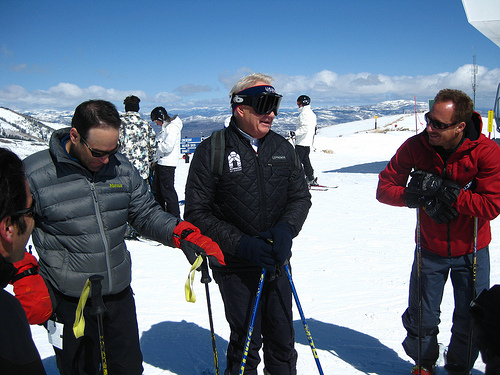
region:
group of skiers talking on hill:
[24, 74, 481, 374]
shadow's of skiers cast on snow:
[116, 283, 435, 373]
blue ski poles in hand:
[208, 263, 370, 365]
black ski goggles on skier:
[226, 79, 305, 126]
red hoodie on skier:
[360, 139, 485, 279]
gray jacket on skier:
[3, 142, 196, 296]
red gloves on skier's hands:
[172, 224, 224, 269]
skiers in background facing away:
[111, 95, 353, 179]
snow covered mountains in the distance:
[38, 80, 425, 160]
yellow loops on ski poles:
[66, 279, 98, 334]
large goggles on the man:
[248, 92, 291, 114]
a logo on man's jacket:
[227, 152, 241, 175]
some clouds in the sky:
[342, 68, 419, 96]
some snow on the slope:
[329, 215, 394, 277]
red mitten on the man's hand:
[180, 226, 215, 258]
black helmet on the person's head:
[152, 108, 169, 118]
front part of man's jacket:
[47, 198, 128, 282]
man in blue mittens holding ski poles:
[242, 238, 314, 374]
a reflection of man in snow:
[326, 319, 386, 372]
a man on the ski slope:
[380, 85, 499, 372]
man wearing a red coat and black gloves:
[408, 88, 489, 260]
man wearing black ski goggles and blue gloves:
[218, 77, 292, 282]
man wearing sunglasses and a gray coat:
[38, 101, 130, 286]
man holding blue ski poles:
[223, 72, 325, 373]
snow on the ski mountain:
[313, 208, 399, 316]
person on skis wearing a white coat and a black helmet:
[294, 93, 319, 188]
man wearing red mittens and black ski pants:
[36, 100, 224, 370]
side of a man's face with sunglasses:
[0, 146, 35, 265]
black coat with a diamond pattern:
[192, 128, 312, 249]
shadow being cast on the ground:
[326, 315, 404, 371]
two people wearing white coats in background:
[151, 93, 358, 213]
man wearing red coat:
[375, 88, 499, 274]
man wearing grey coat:
[19, 97, 228, 331]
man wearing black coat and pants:
[181, 66, 328, 368]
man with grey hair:
[176, 64, 322, 369]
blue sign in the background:
[170, 132, 210, 164]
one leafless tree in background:
[463, 48, 486, 128]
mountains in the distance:
[17, 95, 489, 137]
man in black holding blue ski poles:
[198, 64, 340, 364]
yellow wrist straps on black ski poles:
[55, 249, 213, 336]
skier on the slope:
[201, 54, 294, 374]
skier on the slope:
[384, 80, 486, 365]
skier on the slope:
[37, 93, 174, 373]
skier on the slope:
[153, 97, 190, 220]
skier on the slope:
[110, 93, 152, 181]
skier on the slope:
[287, 81, 330, 183]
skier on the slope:
[1, 150, 46, 371]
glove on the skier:
[185, 228, 221, 275]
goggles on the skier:
[250, 92, 285, 114]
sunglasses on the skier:
[421, 113, 451, 128]